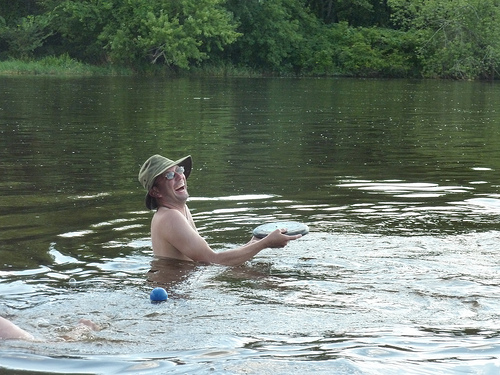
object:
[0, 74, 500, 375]
water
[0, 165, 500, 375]
ripples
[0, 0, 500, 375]
ball water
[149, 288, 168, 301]
ball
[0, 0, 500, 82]
trees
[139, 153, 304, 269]
fair-skinned man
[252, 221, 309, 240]
frisbee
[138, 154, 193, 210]
hat